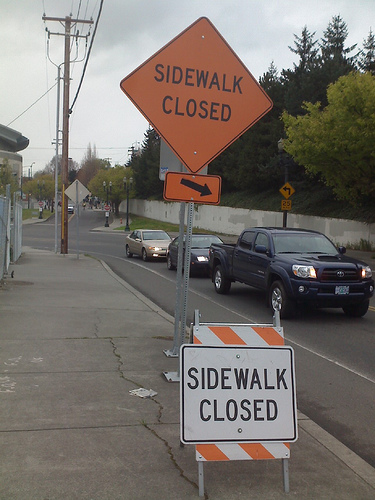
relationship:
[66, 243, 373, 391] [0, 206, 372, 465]
line on road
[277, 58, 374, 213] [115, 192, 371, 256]
tree behind wall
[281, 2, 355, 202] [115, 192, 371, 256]
tree behind wall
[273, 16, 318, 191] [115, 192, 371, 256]
tree behind wall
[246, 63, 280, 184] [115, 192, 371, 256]
tree behind wall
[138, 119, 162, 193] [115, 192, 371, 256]
tree behind wall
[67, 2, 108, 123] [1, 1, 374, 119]
cord in air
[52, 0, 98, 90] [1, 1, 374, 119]
cord in air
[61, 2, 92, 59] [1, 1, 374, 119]
cord in air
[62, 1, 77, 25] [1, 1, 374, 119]
cord in air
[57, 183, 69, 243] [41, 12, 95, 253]
board on pole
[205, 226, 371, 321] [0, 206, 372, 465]
car on street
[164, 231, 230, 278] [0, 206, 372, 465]
car on street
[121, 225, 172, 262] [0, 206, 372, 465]
car on street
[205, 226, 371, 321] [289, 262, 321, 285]
car has lights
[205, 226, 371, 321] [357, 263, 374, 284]
car has lights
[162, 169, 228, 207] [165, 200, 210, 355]
sign on pole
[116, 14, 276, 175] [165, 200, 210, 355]
sign on pole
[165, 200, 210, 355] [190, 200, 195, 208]
pole has holes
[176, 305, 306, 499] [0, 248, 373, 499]
sign on sidewalk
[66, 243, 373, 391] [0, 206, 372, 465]
line on street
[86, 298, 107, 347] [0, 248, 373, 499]
cracks on sidewalk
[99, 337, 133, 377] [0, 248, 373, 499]
cracks on sidewalk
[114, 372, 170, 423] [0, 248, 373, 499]
cracks on sidewalk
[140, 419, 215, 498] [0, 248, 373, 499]
cracks on sidewalk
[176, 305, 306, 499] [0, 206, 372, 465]
sign near road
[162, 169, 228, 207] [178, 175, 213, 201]
sign has arrow